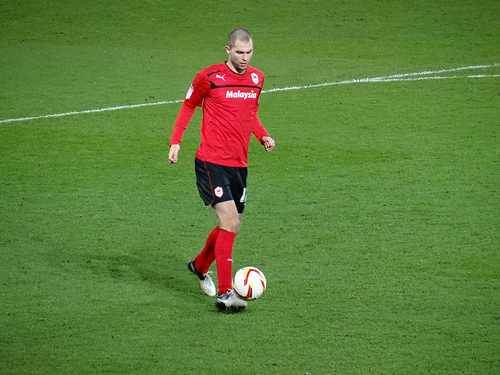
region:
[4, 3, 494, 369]
green soccer field with shadow of player behind him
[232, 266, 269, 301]
white soccer ball with curved red lines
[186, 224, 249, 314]
gray and black shoes with red socks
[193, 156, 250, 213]
black shorts with a red pinstripe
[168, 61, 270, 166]
red long sleeve shirt with a black stripe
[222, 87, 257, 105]
name of the team in white on a red background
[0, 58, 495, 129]
white chalk lines in the green grass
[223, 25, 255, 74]
head of a soccer player with thinning black hair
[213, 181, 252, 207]
white logos on black shorts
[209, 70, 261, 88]
white logos on a red shirt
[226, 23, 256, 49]
Man has short hair.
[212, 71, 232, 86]
White puma on jersey.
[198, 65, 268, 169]
Man wearing red shirt.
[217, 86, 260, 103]
White writing on man's shirt.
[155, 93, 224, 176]
Man wearing long sleeves.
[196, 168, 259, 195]
Man wearing black shorts.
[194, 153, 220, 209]
Red stripe down side of shorts.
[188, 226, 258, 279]
Man wearing red socks.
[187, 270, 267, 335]
Man wearing tennis shoes.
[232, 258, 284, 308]
Soccer ball near man's feet.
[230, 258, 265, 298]
a red and white soccer ball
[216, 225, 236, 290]
a long red sock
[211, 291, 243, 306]
a black soccer shoe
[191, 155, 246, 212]
a man's black shorts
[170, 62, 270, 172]
a man's long red shirt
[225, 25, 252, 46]
a man's short cut hair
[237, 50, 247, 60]
the nose of a man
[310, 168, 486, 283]
a section of green grass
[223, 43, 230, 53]
the ear of a man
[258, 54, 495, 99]
a long white line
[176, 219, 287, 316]
a man with red socks and shoes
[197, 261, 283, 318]
ball near the man's leg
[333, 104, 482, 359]
a play ground full of green grass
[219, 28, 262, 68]
head of the person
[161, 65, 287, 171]
a person wearing red color t-shirt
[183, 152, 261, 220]
a man wearing red color shorts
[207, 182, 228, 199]
a symbol on the black color shorts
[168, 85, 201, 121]
elbow of the person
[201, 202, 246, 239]
knee of the person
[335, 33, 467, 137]
ground marked with white color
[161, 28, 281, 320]
A man on a grass field.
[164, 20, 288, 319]
The man is kicking a soccer ball.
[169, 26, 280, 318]
The player is wearing a red and black uniform.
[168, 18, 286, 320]
The player is on a grass soccer field.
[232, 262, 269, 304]
The soccer ball is white, red and yellow.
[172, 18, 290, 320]
The man is wearing a red shirt.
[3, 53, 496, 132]
White paint lines on the soccer field.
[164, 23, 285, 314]
The man is wearing black shorts.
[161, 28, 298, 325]
The man is looking down at the ball.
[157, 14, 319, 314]
A soccer player.